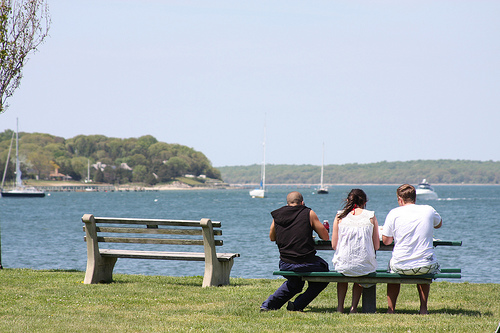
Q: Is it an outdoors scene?
A: Yes, it is outdoors.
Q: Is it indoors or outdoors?
A: It is outdoors.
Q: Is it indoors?
A: No, it is outdoors.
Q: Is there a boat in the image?
A: Yes, there is a boat.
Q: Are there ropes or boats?
A: Yes, there is a boat.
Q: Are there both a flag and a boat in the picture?
A: No, there is a boat but no flags.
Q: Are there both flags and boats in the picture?
A: No, there is a boat but no flags.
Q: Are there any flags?
A: No, there are no flags.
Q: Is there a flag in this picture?
A: No, there are no flags.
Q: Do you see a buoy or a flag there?
A: No, there are no flags or buoys.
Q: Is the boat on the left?
A: Yes, the boat is on the left of the image.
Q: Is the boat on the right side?
A: No, the boat is on the left of the image.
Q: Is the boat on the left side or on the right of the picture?
A: The boat is on the left of the image.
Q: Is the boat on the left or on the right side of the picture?
A: The boat is on the left of the image.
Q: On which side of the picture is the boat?
A: The boat is on the left of the image.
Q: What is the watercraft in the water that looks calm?
A: The watercraft is a boat.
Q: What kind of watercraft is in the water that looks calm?
A: The watercraft is a boat.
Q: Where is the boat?
A: The boat is in the water.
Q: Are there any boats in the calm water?
A: Yes, there is a boat in the water.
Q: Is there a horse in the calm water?
A: No, there is a boat in the water.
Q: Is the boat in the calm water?
A: Yes, the boat is in the water.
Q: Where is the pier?
A: The pier is on the shore.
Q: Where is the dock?
A: The pier is on the shore.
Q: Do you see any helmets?
A: No, there are no helmets.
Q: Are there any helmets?
A: No, there are no helmets.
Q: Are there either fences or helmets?
A: No, there are no helmets or fences.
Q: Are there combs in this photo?
A: No, there are no combs.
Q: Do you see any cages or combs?
A: No, there are no combs or cages.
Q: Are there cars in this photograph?
A: No, there are no cars.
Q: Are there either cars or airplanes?
A: No, there are no cars or airplanes.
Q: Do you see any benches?
A: Yes, there is a bench.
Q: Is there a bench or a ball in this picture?
A: Yes, there is a bench.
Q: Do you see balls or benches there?
A: Yes, there is a bench.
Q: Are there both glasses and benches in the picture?
A: No, there is a bench but no glasses.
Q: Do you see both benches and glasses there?
A: No, there is a bench but no glasses.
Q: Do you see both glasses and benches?
A: No, there is a bench but no glasses.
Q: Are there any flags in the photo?
A: No, there are no flags.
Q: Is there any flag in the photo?
A: No, there are no flags.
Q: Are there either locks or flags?
A: No, there are no flags or locks.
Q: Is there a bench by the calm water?
A: Yes, there is a bench by the water.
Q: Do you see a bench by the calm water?
A: Yes, there is a bench by the water.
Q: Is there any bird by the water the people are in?
A: No, there is a bench by the water.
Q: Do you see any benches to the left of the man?
A: Yes, there is a bench to the left of the man.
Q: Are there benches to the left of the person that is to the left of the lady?
A: Yes, there is a bench to the left of the man.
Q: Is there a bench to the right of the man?
A: No, the bench is to the left of the man.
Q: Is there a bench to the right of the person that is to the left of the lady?
A: No, the bench is to the left of the man.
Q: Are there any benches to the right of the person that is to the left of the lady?
A: No, the bench is to the left of the man.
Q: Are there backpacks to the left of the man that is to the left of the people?
A: No, there is a bench to the left of the man.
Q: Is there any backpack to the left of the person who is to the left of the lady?
A: No, there is a bench to the left of the man.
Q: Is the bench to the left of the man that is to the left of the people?
A: Yes, the bench is to the left of the man.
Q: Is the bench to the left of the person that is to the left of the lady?
A: Yes, the bench is to the left of the man.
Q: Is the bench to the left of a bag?
A: No, the bench is to the left of the man.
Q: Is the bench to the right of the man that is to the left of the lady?
A: No, the bench is to the left of the man.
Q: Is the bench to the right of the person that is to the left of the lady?
A: No, the bench is to the left of the man.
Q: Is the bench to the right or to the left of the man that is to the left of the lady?
A: The bench is to the left of the man.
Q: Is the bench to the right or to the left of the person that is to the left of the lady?
A: The bench is to the left of the man.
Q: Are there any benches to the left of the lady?
A: Yes, there is a bench to the left of the lady.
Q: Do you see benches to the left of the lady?
A: Yes, there is a bench to the left of the lady.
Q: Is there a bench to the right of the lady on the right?
A: No, the bench is to the left of the lady.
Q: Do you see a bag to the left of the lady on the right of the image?
A: No, there is a bench to the left of the lady.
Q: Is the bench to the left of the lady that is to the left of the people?
A: Yes, the bench is to the left of the lady.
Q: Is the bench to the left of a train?
A: No, the bench is to the left of the lady.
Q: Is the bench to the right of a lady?
A: No, the bench is to the left of a lady.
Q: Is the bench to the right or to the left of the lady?
A: The bench is to the left of the lady.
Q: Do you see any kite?
A: No, there are no kites.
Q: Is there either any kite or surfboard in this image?
A: No, there are no kites or surfboards.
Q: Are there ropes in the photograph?
A: No, there are no ropes.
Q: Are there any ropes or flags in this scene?
A: No, there are no ropes or flags.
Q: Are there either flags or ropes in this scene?
A: No, there are no ropes or flags.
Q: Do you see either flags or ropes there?
A: No, there are no ropes or flags.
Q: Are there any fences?
A: No, there are no fences.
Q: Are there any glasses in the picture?
A: No, there are no glasses.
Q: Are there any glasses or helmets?
A: No, there are no glasses or helmets.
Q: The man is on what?
A: The man is on the bench.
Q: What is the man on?
A: The man is on the bench.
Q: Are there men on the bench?
A: Yes, there is a man on the bench.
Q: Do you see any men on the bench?
A: Yes, there is a man on the bench.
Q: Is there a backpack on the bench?
A: No, there is a man on the bench.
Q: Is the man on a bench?
A: Yes, the man is on a bench.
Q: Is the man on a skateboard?
A: No, the man is on a bench.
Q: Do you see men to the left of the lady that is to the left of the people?
A: Yes, there is a man to the left of the lady.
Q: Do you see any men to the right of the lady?
A: No, the man is to the left of the lady.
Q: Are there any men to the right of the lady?
A: No, the man is to the left of the lady.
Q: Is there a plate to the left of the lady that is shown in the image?
A: No, there is a man to the left of the lady.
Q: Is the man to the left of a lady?
A: Yes, the man is to the left of a lady.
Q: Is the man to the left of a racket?
A: No, the man is to the left of a lady.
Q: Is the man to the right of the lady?
A: No, the man is to the left of the lady.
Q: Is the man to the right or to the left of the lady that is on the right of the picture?
A: The man is to the left of the lady.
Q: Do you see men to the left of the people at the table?
A: Yes, there is a man to the left of the people.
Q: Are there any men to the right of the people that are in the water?
A: No, the man is to the left of the people.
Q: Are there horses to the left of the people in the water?
A: No, there is a man to the left of the people.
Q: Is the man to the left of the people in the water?
A: Yes, the man is to the left of the people.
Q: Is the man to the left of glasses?
A: No, the man is to the left of the people.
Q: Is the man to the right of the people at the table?
A: No, the man is to the left of the people.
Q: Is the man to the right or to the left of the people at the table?
A: The man is to the left of the people.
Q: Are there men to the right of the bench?
A: Yes, there is a man to the right of the bench.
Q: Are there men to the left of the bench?
A: No, the man is to the right of the bench.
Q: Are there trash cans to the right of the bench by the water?
A: No, there is a man to the right of the bench.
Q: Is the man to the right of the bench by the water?
A: Yes, the man is to the right of the bench.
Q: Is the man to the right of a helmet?
A: No, the man is to the right of the bench.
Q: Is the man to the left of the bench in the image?
A: No, the man is to the right of the bench.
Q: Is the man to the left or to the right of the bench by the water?
A: The man is to the right of the bench.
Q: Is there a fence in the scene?
A: No, there are no fences.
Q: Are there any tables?
A: Yes, there is a table.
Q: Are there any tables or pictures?
A: Yes, there is a table.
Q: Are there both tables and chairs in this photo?
A: No, there is a table but no chairs.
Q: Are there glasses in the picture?
A: No, there are no glasses.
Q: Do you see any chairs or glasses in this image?
A: No, there are no glasses or chairs.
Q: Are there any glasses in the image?
A: No, there are no glasses.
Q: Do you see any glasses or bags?
A: No, there are no glasses or bags.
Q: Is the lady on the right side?
A: Yes, the lady is on the right of the image.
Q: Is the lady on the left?
A: No, the lady is on the right of the image.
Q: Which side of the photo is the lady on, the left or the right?
A: The lady is on the right of the image.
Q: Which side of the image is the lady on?
A: The lady is on the right of the image.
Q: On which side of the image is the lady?
A: The lady is on the right of the image.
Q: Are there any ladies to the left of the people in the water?
A: Yes, there is a lady to the left of the people.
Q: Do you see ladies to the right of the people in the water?
A: No, the lady is to the left of the people.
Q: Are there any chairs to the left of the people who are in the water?
A: No, there is a lady to the left of the people.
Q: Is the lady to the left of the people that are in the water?
A: Yes, the lady is to the left of the people.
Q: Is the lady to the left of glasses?
A: No, the lady is to the left of the people.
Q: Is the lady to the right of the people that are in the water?
A: No, the lady is to the left of the people.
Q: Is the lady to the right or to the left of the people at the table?
A: The lady is to the left of the people.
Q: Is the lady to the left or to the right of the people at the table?
A: The lady is to the left of the people.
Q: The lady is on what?
A: The lady is on the bench.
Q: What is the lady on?
A: The lady is on the bench.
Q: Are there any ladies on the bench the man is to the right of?
A: Yes, there is a lady on the bench.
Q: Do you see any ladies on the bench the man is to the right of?
A: Yes, there is a lady on the bench.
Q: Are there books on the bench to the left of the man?
A: No, there is a lady on the bench.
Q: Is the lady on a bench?
A: Yes, the lady is on a bench.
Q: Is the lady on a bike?
A: No, the lady is on a bench.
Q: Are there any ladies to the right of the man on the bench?
A: Yes, there is a lady to the right of the man.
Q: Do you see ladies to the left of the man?
A: No, the lady is to the right of the man.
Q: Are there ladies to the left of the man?
A: No, the lady is to the right of the man.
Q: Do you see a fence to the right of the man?
A: No, there is a lady to the right of the man.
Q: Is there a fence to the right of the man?
A: No, there is a lady to the right of the man.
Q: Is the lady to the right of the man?
A: Yes, the lady is to the right of the man.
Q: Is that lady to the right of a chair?
A: No, the lady is to the right of the man.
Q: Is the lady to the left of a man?
A: No, the lady is to the right of a man.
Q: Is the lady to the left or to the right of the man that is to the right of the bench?
A: The lady is to the right of the man.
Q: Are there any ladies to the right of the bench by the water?
A: Yes, there is a lady to the right of the bench.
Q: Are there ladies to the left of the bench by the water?
A: No, the lady is to the right of the bench.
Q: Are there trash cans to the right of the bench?
A: No, there is a lady to the right of the bench.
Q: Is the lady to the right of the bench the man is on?
A: Yes, the lady is to the right of the bench.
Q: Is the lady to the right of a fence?
A: No, the lady is to the right of the bench.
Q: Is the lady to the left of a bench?
A: No, the lady is to the right of a bench.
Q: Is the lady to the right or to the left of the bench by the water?
A: The lady is to the right of the bench.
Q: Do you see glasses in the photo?
A: No, there are no glasses.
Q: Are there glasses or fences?
A: No, there are no glasses or fences.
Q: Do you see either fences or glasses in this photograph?
A: No, there are no glasses or fences.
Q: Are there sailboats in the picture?
A: Yes, there is a sailboat.